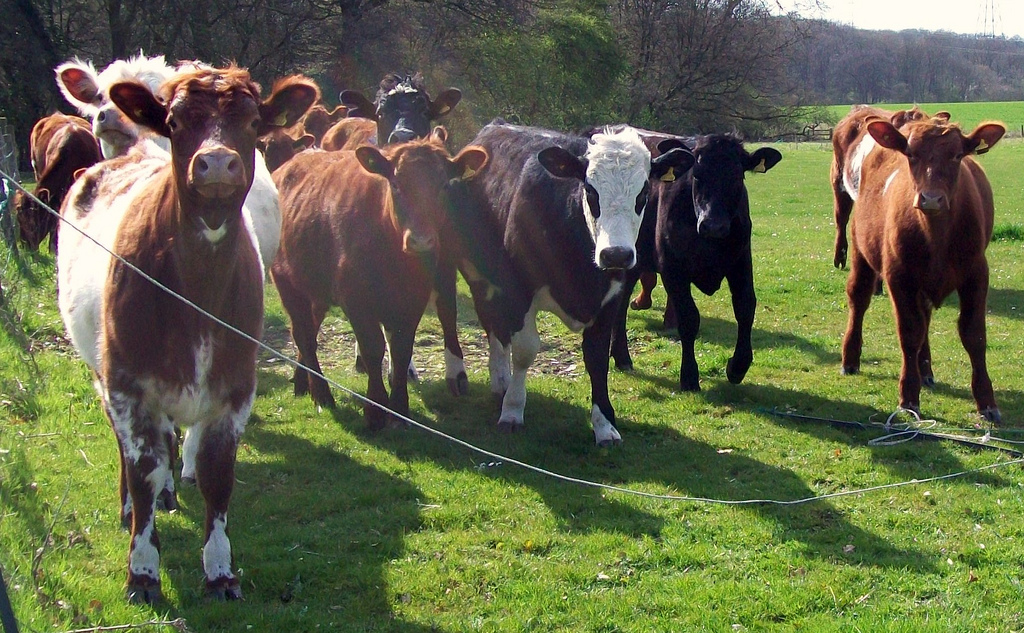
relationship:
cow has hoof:
[51, 64, 319, 603] [121, 564, 167, 610]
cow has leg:
[51, 64, 319, 603] [101, 383, 173, 606]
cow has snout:
[51, 64, 319, 603] [183, 143, 248, 202]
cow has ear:
[51, 64, 319, 603] [106, 79, 167, 136]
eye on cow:
[163, 103, 186, 137] [51, 64, 319, 603]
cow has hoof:
[457, 116, 689, 452] [591, 419, 622, 461]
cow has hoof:
[457, 116, 689, 452] [499, 400, 528, 431]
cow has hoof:
[51, 64, 319, 603] [203, 575, 242, 602]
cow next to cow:
[267, 130, 497, 431] [457, 116, 689, 452]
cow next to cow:
[267, 130, 497, 431] [51, 64, 319, 603]